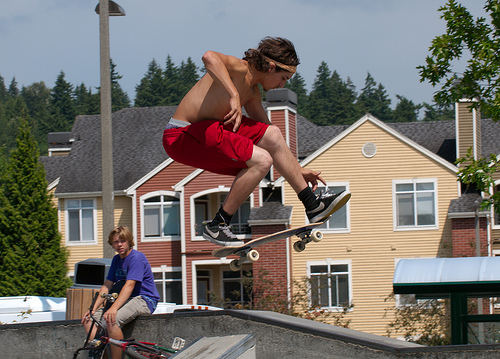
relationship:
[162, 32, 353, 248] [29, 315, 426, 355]
skateboarder high above ground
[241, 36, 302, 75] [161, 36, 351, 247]
hair on boy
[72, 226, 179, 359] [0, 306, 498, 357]
boy on ramp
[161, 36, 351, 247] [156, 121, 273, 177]
boy wearing shorts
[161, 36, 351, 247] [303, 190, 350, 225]
boy wearing shoe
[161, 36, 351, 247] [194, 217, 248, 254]
boy wearing shoe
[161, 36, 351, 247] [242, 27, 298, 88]
boy with hair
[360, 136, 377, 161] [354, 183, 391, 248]
window with siding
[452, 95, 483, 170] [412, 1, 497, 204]
chimney covered by tree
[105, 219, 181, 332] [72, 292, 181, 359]
boy with bicycle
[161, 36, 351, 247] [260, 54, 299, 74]
boy wearing headband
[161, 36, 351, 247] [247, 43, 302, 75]
boy wearing headband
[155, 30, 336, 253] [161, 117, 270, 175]
boy wearing boxers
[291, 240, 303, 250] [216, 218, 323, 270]
wheel on board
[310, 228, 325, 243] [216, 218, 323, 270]
wheel on board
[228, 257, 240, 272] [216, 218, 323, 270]
wheel on board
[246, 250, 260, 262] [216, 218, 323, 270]
wheel on board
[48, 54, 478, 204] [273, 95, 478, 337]
roofs on houses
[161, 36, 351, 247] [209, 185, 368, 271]
boy skating skateboard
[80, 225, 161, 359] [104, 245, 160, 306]
kid wearing shirt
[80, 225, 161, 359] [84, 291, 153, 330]
kid wearing shorts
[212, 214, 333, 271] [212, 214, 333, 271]
board has board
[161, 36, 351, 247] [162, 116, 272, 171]
boy has shorts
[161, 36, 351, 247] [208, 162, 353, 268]
boy riding skateboard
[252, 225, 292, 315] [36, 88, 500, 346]
brick siding on condominium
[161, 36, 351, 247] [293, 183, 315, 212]
boy wearing sock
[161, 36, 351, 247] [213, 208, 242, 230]
boy wearing sock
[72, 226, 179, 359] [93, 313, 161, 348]
boy with a bicycle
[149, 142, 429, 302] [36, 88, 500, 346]
condominium attached to condominium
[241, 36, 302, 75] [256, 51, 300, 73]
hair has headband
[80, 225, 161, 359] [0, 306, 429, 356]
kid sitting on ledge